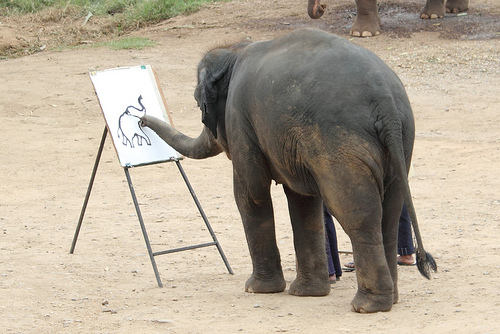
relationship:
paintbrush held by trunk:
[127, 111, 143, 120] [138, 112, 228, 159]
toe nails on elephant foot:
[243, 286, 258, 296] [287, 254, 335, 309]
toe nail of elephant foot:
[345, 26, 353, 36] [345, 11, 386, 38]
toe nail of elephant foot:
[350, 27, 361, 40] [345, 11, 386, 38]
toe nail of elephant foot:
[359, 27, 374, 38] [345, 11, 386, 38]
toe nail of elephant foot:
[371, 29, 384, 39] [345, 11, 386, 38]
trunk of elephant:
[127, 108, 191, 158] [139, 25, 436, 311]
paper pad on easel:
[90, 62, 185, 166] [68, 67, 236, 289]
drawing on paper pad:
[115, 90, 155, 150] [87, 61, 185, 167]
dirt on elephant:
[269, 117, 387, 225] [139, 25, 436, 311]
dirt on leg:
[269, 117, 387, 225] [319, 151, 395, 313]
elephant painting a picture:
[139, 25, 436, 311] [93, 57, 179, 167]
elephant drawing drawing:
[181, 48, 435, 311] [115, 90, 158, 151]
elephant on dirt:
[139, 25, 436, 311] [6, 11, 498, 329]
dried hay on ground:
[1, 10, 111, 47] [1, 67, 73, 275]